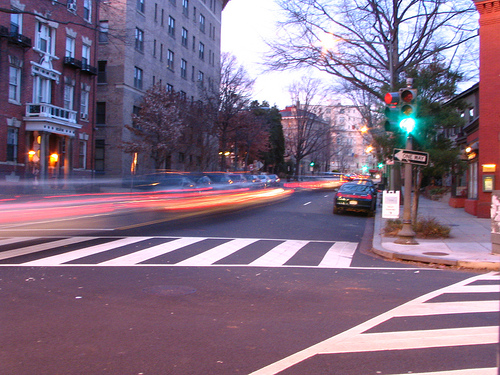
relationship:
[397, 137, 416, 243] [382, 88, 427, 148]
pole on traffic signal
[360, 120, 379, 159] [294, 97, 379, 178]
lights on building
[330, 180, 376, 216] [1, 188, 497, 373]
black care on road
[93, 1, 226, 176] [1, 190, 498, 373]
building on roadside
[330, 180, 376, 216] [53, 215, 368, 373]
black care zooming down street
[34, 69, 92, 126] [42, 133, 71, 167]
terrace over entry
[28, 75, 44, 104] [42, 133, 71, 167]
columns over entry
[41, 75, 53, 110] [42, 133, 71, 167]
columns over entry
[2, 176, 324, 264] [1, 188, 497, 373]
cars on road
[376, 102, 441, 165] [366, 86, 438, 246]
singal on pole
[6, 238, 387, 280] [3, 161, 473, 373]
stripes on street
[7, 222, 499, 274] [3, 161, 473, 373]
crosswalk on street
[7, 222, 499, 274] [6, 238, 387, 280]
crosswalk has stripes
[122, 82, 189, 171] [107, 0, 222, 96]
tree in front of building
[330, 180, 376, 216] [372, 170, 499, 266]
black care parked by curb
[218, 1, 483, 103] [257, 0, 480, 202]
clear sky behind tree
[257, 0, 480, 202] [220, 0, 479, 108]
tree against sky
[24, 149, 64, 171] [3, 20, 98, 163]
lights outside building